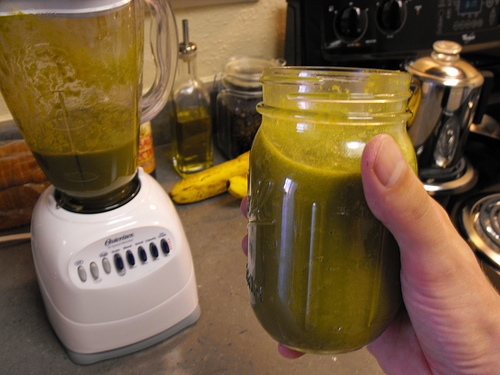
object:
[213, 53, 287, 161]
container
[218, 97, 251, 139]
dark contents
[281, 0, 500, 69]
stove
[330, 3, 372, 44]
control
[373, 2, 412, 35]
control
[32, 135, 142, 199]
green liquid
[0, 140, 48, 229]
bread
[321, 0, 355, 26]
knobs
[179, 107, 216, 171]
oil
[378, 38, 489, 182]
coffee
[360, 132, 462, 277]
thumb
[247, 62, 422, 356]
jar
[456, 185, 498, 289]
burner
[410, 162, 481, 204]
burner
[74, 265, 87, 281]
buttons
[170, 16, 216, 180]
bottle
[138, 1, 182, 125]
handle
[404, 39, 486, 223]
kettle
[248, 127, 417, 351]
salsa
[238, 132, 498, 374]
hand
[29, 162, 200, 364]
base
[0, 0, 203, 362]
blender